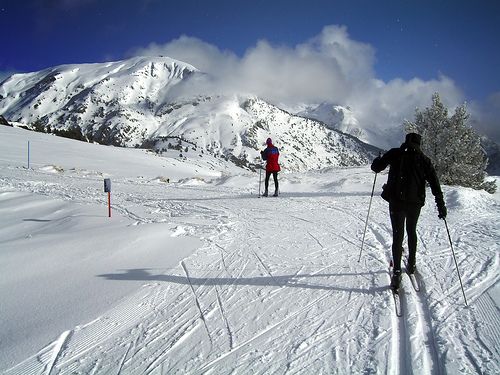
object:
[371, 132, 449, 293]
person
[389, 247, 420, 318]
snow skis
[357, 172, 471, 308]
ski poles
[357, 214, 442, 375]
tracks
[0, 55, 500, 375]
snow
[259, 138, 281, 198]
person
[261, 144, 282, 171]
coat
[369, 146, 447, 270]
black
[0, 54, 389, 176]
mountain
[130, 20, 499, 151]
clouds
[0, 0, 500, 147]
sky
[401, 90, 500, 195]
tree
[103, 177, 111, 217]
post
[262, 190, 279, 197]
skis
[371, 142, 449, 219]
jacket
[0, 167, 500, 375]
track marks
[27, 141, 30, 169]
pole